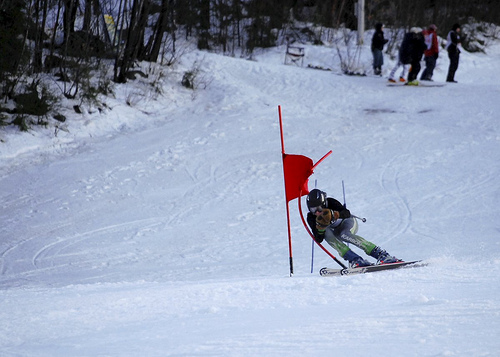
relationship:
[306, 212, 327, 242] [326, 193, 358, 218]
arm of a person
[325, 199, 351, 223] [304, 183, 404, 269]
arm of a person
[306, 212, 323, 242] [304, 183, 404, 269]
arm of a person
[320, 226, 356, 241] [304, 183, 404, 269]
knee of a person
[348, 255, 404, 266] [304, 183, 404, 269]
feet of a person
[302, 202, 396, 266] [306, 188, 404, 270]
body of a man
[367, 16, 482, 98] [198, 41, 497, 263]
people in snow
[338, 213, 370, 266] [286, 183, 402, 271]
knee of person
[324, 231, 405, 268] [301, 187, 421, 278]
leg of person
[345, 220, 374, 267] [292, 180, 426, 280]
leg of person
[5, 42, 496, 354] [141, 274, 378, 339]
snow on ground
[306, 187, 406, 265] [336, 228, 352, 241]
man bending knee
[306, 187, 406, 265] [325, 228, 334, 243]
man bending knee